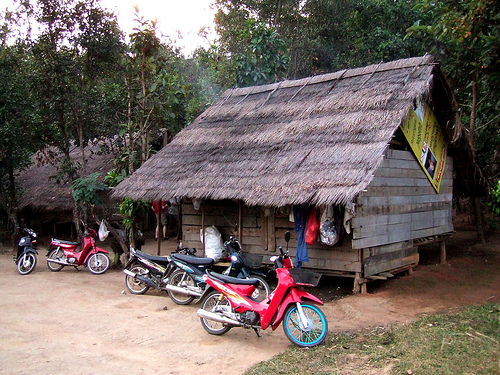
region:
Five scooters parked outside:
[4, 228, 374, 338]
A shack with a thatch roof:
[205, 69, 435, 291]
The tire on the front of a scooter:
[283, 297, 330, 354]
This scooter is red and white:
[205, 272, 303, 324]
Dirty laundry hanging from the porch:
[289, 205, 341, 265]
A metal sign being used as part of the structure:
[386, 78, 453, 203]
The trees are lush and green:
[26, 75, 136, 119]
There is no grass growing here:
[22, 295, 232, 352]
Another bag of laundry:
[198, 224, 228, 260]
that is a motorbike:
[15, 222, 45, 268]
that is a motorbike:
[45, 225, 122, 270]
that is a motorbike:
[132, 250, 217, 295]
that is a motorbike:
[207, 261, 317, 336]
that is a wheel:
[277, 308, 325, 344]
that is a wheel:
[198, 292, 234, 332]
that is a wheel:
[163, 270, 198, 307]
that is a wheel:
[125, 267, 150, 292]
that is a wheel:
[85, 247, 110, 275]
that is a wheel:
[18, 254, 45, 276]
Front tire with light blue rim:
[283, 303, 328, 347]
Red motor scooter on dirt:
[192, 253, 327, 346]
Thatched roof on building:
[113, 55, 438, 207]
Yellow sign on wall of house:
[401, 84, 453, 191]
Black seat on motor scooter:
[206, 270, 268, 285]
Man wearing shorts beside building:
[148, 199, 168, 240]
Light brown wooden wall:
[350, 148, 457, 250]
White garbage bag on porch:
[200, 224, 224, 258]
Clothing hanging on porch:
[284, 204, 315, 262]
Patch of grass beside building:
[250, 299, 497, 373]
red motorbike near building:
[198, 230, 329, 351]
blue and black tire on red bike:
[282, 303, 329, 351]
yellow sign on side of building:
[398, 96, 446, 193]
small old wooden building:
[111, 51, 493, 293]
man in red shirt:
[147, 199, 172, 241]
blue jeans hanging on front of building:
[292, 204, 307, 268]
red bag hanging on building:
[303, 210, 318, 245]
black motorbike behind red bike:
[158, 223, 275, 306]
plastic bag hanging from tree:
[95, 218, 112, 242]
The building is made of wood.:
[363, 173, 467, 262]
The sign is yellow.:
[388, 98, 448, 196]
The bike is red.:
[183, 270, 330, 346]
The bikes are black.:
[129, 244, 267, 314]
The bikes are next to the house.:
[8, 74, 359, 366]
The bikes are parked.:
[18, 194, 333, 359]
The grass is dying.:
[262, 316, 499, 372]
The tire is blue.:
[286, 305, 332, 355]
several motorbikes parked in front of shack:
[10, 213, 331, 348]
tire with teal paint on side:
[285, 306, 332, 348]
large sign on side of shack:
[402, 95, 454, 190]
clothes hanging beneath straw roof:
[291, 203, 352, 268]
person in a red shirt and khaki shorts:
[149, 193, 170, 240]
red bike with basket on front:
[197, 242, 327, 350]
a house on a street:
[121, 43, 453, 286]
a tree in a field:
[9, 5, 121, 242]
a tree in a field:
[98, 7, 186, 180]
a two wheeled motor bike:
[196, 245, 326, 350]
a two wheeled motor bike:
[169, 245, 266, 307]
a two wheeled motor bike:
[119, 245, 196, 298]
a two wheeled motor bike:
[43, 218, 110, 278]